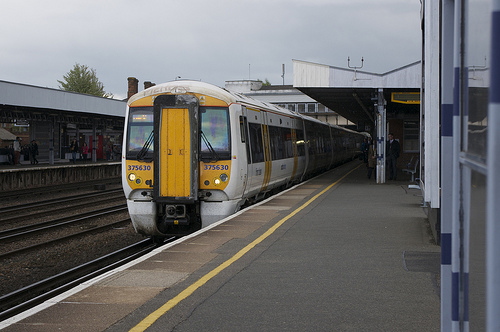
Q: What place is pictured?
A: It is a walkway.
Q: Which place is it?
A: It is a walkway.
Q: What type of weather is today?
A: It is cloudy.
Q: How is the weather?
A: It is cloudy.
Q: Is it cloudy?
A: Yes, it is cloudy.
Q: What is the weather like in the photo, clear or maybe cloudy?
A: It is cloudy.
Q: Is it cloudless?
A: No, it is cloudy.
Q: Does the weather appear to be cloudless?
A: No, it is cloudy.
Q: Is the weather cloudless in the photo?
A: No, it is cloudy.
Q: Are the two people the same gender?
A: No, they are both male and female.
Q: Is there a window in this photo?
A: Yes, there is a window.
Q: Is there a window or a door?
A: Yes, there is a window.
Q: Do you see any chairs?
A: No, there are no chairs.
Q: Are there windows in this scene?
A: Yes, there is a window.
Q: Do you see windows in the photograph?
A: Yes, there is a window.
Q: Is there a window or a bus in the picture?
A: Yes, there is a window.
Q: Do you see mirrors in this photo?
A: No, there are no mirrors.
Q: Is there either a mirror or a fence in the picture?
A: No, there are no mirrors or fences.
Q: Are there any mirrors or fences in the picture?
A: No, there are no mirrors or fences.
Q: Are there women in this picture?
A: Yes, there is a woman.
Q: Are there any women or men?
A: Yes, there is a woman.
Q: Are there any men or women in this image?
A: Yes, there is a woman.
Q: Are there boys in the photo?
A: No, there are no boys.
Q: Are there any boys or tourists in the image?
A: No, there are no boys or tourists.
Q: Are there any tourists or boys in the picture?
A: No, there are no boys or tourists.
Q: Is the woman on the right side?
A: Yes, the woman is on the right of the image.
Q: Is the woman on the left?
A: No, the woman is on the right of the image.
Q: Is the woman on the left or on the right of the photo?
A: The woman is on the right of the image.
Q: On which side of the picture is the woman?
A: The woman is on the right of the image.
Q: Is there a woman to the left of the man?
A: Yes, there is a woman to the left of the man.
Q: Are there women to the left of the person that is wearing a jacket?
A: Yes, there is a woman to the left of the man.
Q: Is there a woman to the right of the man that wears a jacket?
A: No, the woman is to the left of the man.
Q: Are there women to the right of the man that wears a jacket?
A: No, the woman is to the left of the man.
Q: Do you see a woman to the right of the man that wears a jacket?
A: No, the woman is to the left of the man.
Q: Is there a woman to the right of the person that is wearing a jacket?
A: No, the woman is to the left of the man.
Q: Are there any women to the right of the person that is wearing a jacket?
A: No, the woman is to the left of the man.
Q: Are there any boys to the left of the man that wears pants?
A: No, there is a woman to the left of the man.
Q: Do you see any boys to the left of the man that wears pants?
A: No, there is a woman to the left of the man.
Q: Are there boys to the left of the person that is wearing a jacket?
A: No, there is a woman to the left of the man.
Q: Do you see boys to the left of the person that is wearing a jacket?
A: No, there is a woman to the left of the man.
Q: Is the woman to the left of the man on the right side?
A: Yes, the woman is to the left of the man.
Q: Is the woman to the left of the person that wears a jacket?
A: Yes, the woman is to the left of the man.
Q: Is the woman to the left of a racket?
A: No, the woman is to the left of the man.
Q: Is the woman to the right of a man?
A: No, the woman is to the left of a man.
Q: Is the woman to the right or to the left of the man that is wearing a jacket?
A: The woman is to the left of the man.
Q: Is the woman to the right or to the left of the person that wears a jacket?
A: The woman is to the left of the man.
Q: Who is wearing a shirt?
A: The woman is wearing a shirt.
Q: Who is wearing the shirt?
A: The woman is wearing a shirt.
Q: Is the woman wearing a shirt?
A: Yes, the woman is wearing a shirt.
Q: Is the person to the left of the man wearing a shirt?
A: Yes, the woman is wearing a shirt.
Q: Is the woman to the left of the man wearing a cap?
A: No, the woman is wearing a shirt.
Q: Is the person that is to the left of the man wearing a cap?
A: No, the woman is wearing a shirt.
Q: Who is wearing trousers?
A: The woman is wearing trousers.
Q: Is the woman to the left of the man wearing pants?
A: Yes, the woman is wearing pants.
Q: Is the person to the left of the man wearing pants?
A: Yes, the woman is wearing pants.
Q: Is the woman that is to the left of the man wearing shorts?
A: No, the woman is wearing pants.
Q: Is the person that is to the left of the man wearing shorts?
A: No, the woman is wearing pants.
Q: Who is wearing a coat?
A: The woman is wearing a coat.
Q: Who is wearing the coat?
A: The woman is wearing a coat.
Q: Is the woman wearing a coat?
A: Yes, the woman is wearing a coat.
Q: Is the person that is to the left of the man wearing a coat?
A: Yes, the woman is wearing a coat.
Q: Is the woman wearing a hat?
A: No, the woman is wearing a coat.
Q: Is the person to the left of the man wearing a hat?
A: No, the woman is wearing a coat.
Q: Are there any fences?
A: No, there are no fences.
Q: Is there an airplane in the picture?
A: No, there are no airplanes.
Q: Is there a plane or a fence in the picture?
A: No, there are no airplanes or fences.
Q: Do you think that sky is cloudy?
A: Yes, the sky is cloudy.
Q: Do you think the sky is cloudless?
A: No, the sky is cloudy.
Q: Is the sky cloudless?
A: No, the sky is cloudy.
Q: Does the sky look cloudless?
A: No, the sky is cloudy.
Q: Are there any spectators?
A: No, there are no spectators.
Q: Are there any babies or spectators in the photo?
A: No, there are no spectators or babies.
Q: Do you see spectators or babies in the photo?
A: No, there are no spectators or babies.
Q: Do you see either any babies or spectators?
A: No, there are no spectators or babies.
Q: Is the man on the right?
A: Yes, the man is on the right of the image.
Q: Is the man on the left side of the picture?
A: No, the man is on the right of the image.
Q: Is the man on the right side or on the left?
A: The man is on the right of the image.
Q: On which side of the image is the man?
A: The man is on the right of the image.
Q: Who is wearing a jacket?
A: The man is wearing a jacket.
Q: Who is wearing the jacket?
A: The man is wearing a jacket.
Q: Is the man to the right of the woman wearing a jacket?
A: Yes, the man is wearing a jacket.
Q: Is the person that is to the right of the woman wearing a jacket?
A: Yes, the man is wearing a jacket.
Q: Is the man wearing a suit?
A: No, the man is wearing a jacket.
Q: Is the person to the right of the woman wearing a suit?
A: No, the man is wearing a jacket.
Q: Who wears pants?
A: The man wears pants.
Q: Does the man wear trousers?
A: Yes, the man wears trousers.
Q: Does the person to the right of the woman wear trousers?
A: Yes, the man wears trousers.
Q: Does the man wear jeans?
A: No, the man wears trousers.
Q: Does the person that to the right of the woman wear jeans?
A: No, the man wears trousers.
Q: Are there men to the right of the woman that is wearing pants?
A: Yes, there is a man to the right of the woman.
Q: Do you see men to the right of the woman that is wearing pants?
A: Yes, there is a man to the right of the woman.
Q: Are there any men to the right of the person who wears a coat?
A: Yes, there is a man to the right of the woman.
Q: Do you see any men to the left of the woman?
A: No, the man is to the right of the woman.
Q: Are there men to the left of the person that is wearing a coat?
A: No, the man is to the right of the woman.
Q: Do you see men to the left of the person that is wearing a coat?
A: No, the man is to the right of the woman.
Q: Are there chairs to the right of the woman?
A: No, there is a man to the right of the woman.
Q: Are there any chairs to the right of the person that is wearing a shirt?
A: No, there is a man to the right of the woman.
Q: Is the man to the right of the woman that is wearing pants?
A: Yes, the man is to the right of the woman.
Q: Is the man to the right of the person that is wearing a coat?
A: Yes, the man is to the right of the woman.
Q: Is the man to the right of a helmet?
A: No, the man is to the right of the woman.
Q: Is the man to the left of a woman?
A: No, the man is to the right of a woman.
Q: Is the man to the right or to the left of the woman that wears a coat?
A: The man is to the right of the woman.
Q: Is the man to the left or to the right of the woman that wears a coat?
A: The man is to the right of the woman.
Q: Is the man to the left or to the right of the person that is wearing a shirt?
A: The man is to the right of the woman.